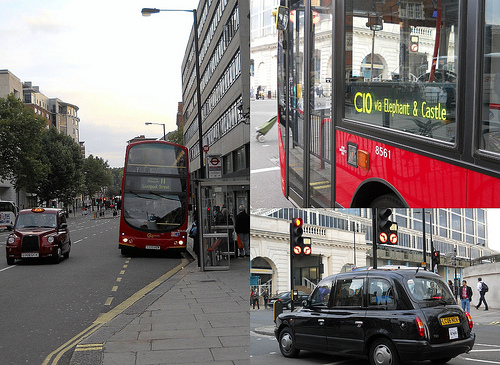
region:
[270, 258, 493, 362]
Black car on the right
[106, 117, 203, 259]
Double decker bus on left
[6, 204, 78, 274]
Red taxi on left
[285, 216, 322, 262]
A stop light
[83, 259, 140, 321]
Yellow dotted lines on street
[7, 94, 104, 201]
A row of trees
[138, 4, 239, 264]
A street light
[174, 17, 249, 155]
A tall beige building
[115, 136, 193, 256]
red double decker bus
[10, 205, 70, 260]
red taxi on city street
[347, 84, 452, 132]
painted sign on window of double decker bus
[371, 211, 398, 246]
traffic signals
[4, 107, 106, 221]
green trees line the city street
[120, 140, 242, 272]
bus is at a stop for waiting riders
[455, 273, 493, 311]
people walking in the background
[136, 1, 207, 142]
street lights on tall poles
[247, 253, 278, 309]
people standing under archway of large building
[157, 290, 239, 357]
decorative pattern on the sidewalk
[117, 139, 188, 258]
A bus is stopped.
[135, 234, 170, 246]
The bus is red.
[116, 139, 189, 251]
The bus is a double decker.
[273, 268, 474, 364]
The cab is black.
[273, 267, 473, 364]
The cab is on the street.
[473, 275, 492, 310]
A man walks down the street.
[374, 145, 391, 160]
A number is on the bus.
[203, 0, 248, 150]
A building is on the street.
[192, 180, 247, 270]
A waiting station is next to the bus.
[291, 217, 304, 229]
The traffic light is red.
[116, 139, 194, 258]
A double decker bus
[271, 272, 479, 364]
A london taxi cab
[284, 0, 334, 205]
Doors of a large bus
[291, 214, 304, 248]
A yellow caution light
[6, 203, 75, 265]
A london cab taxi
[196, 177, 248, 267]
A london bus stop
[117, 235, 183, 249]
The head lights of bus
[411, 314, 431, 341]
Left tail light of cab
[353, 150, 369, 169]
An orange safety reflector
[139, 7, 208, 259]
A tall traffic pole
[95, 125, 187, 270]
red double decker bus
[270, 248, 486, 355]
black car with four doors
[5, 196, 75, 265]
red car with sign on front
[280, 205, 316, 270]
stop light with arrows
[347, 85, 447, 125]
word on bus window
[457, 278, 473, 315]
man wearing black jacket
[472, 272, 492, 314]
man wearing black backpack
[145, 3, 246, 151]
building with many windows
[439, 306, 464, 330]
license plate in yellow